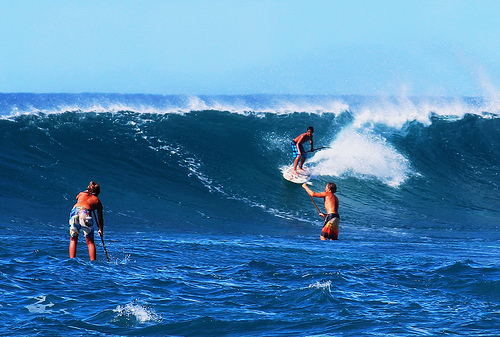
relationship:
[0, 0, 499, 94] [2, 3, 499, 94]
clouds on sky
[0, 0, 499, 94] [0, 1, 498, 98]
clouds in blue sky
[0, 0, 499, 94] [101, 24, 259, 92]
clouds in sky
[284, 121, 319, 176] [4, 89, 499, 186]
guy surfing wave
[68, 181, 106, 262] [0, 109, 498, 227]
guy paddling to wave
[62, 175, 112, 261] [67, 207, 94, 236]
guy wearing swimming trunks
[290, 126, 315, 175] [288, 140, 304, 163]
guy wearing swimming trunks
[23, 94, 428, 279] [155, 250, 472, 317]
people in water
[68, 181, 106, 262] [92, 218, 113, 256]
guy with paddle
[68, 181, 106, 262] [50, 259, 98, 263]
guy on board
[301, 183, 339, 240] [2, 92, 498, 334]
guy in water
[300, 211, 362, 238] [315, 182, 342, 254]
shorts on person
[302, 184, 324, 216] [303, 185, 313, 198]
paddle in hand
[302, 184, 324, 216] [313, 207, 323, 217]
paddle in hand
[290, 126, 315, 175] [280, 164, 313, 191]
guy stands on board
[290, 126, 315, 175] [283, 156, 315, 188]
guy on board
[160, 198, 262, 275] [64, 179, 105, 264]
water near person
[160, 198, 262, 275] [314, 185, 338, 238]
water near person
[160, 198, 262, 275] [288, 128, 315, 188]
water near person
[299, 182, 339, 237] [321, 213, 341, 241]
guy wearing shorts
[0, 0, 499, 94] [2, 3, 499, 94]
clouds in sky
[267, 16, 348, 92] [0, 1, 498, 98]
clouds in blue sky